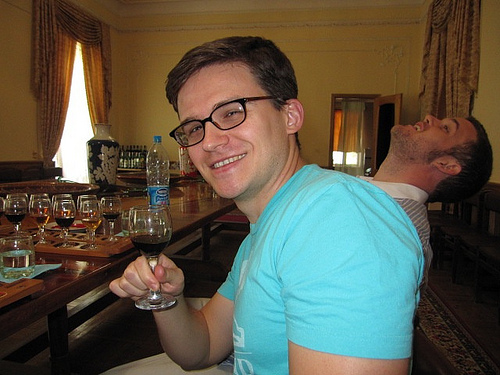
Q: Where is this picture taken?
A: Bar.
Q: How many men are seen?
A: Two.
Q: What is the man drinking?
A: Wine.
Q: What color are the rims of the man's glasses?
A: Black.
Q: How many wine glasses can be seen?
A: Eleven.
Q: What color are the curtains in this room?
A: Tan.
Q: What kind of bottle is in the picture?
A: Water.